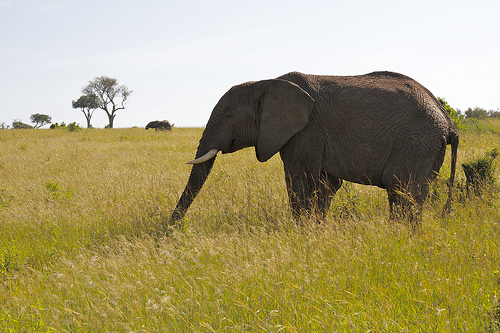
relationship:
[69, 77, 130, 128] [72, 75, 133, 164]
trees growing side by side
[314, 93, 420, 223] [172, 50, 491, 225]
tough skin on an elephant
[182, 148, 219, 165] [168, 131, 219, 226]
tusk on side of trunk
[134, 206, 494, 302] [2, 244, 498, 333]
grass on ground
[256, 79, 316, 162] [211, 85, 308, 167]
ear ear on side of head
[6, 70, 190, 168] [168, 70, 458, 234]
light shining on animal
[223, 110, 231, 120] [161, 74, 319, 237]
eye on side of head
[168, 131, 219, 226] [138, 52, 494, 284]
trunk of an elephant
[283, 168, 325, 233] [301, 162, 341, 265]
leg of an elephant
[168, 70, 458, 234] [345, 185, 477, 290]
animal standing in tall grass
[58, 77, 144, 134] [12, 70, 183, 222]
trees and bushes on horizon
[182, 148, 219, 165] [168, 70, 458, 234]
tusk tusk of an animal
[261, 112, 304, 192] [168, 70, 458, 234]
large left gray ear of an animal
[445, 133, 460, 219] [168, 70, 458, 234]
tail of an animal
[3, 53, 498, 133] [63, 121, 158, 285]
sky over field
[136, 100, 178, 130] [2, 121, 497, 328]
animal in grass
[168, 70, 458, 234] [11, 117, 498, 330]
animal in field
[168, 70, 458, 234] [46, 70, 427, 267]
animal in field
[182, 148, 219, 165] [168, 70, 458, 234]
tusk of animal